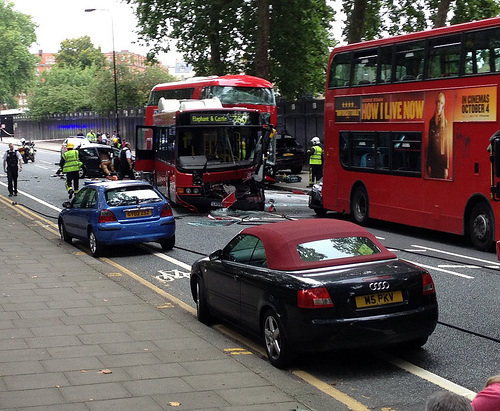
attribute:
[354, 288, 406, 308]
plate — yellow  , black 